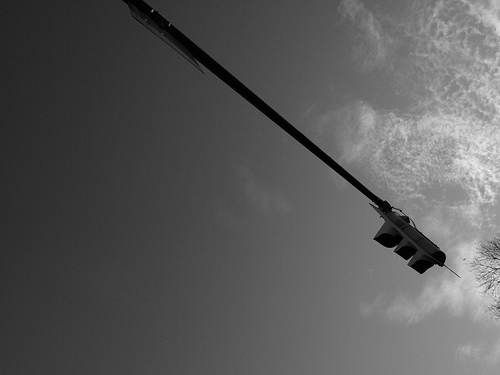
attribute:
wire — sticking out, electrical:
[391, 205, 419, 230]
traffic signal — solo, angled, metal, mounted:
[369, 202, 447, 277]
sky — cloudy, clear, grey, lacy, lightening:
[1, 0, 498, 375]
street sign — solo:
[128, 2, 204, 73]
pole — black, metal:
[123, 0, 394, 213]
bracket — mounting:
[145, 7, 156, 20]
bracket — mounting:
[163, 20, 173, 35]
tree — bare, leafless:
[465, 235, 499, 320]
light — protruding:
[375, 233, 397, 247]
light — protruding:
[395, 243, 413, 259]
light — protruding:
[412, 261, 432, 273]